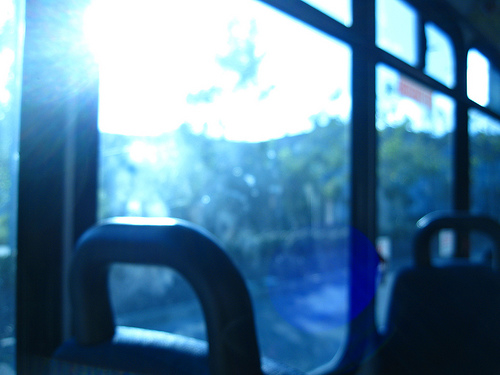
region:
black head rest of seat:
[57, 213, 259, 361]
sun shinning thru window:
[80, 1, 231, 83]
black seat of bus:
[382, 211, 490, 371]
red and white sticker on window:
[395, 71, 435, 106]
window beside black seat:
[212, 45, 351, 237]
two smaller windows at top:
[377, 0, 466, 91]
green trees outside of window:
[379, 125, 439, 190]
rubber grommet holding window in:
[328, 334, 351, 368]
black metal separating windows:
[350, 58, 375, 294]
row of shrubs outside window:
[260, 228, 335, 278]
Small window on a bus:
[467, 44, 489, 114]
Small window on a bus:
[488, 63, 498, 99]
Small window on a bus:
[423, 16, 465, 88]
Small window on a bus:
[373, 2, 418, 65]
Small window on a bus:
[307, 1, 356, 16]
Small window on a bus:
[468, 108, 498, 262]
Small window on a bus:
[369, 55, 460, 334]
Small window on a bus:
[99, 6, 361, 366]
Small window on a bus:
[0, 5, 25, 374]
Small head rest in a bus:
[50, 205, 266, 369]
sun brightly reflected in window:
[97, 0, 357, 170]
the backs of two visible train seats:
[50, 205, 499, 369]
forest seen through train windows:
[107, 114, 498, 330]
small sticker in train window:
[396, 75, 436, 110]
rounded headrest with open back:
[64, 219, 251, 359]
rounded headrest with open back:
[406, 205, 498, 260]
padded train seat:
[55, 329, 282, 373]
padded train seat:
[377, 246, 499, 361]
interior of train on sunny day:
[4, 3, 498, 368]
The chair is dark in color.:
[64, 215, 254, 374]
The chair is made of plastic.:
[61, 224, 261, 361]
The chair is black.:
[387, 207, 497, 372]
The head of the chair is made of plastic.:
[413, 206, 498, 262]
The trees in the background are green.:
[253, 151, 337, 214]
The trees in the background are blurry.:
[251, 143, 348, 218]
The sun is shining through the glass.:
[78, 6, 174, 94]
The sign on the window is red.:
[398, 73, 435, 107]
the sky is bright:
[70, 0, 222, 119]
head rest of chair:
[43, 205, 265, 366]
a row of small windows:
[374, 5, 499, 90]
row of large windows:
[108, 80, 499, 354]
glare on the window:
[53, 3, 293, 123]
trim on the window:
[343, 20, 388, 365]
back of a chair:
[382, 257, 496, 373]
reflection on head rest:
[103, 208, 187, 249]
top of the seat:
[110, 323, 221, 372]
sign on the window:
[396, 77, 438, 114]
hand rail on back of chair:
[53, 204, 264, 374]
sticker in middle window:
[395, 66, 435, 107]